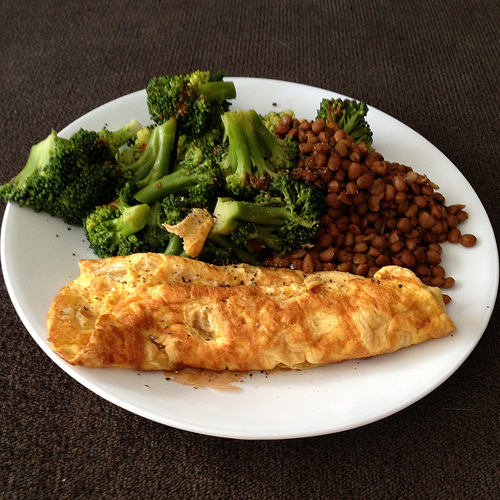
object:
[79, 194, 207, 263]
broccoli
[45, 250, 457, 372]
omelette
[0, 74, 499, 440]
plate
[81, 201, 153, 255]
broccoli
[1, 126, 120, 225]
broccoli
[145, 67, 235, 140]
broccoli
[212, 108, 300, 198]
broccoli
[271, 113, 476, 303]
bean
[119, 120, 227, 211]
broccoli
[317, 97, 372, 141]
broccoli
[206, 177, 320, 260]
broccoli